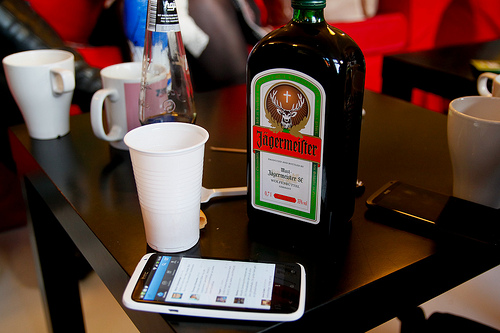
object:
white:
[190, 310, 224, 318]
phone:
[123, 250, 310, 323]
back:
[276, 261, 303, 312]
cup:
[0, 50, 79, 141]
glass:
[242, 0, 370, 231]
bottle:
[134, 0, 198, 128]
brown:
[327, 229, 399, 267]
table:
[5, 68, 498, 333]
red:
[376, 25, 379, 34]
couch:
[22, 0, 127, 68]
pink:
[128, 86, 140, 99]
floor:
[0, 223, 137, 333]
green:
[248, 67, 320, 138]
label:
[245, 65, 328, 225]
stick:
[210, 145, 248, 153]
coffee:
[14, 50, 52, 65]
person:
[188, 0, 251, 78]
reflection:
[51, 159, 124, 202]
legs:
[37, 264, 93, 333]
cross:
[283, 91, 292, 104]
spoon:
[199, 184, 248, 205]